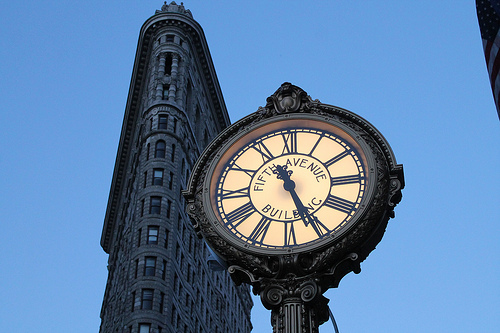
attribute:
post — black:
[269, 301, 318, 331]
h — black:
[267, 161, 279, 173]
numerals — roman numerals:
[224, 199, 259, 228]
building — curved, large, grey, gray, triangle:
[90, 6, 250, 331]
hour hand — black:
[180, 102, 391, 264]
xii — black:
[281, 132, 299, 152]